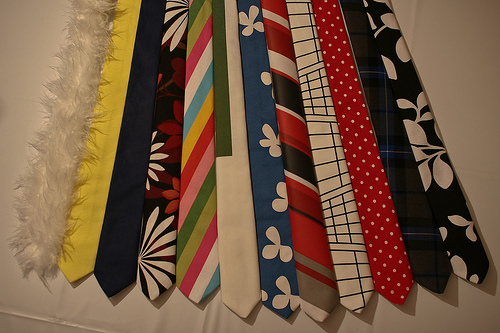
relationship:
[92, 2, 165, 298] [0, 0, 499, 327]
black tie laying on background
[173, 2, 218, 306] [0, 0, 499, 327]
necktie laying on background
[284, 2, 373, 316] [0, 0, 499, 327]
necktie laying on background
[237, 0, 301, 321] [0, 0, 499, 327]
necktie laying on background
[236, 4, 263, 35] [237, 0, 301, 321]
white flowers on necktie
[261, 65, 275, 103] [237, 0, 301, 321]
white flowers on necktie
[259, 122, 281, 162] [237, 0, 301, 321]
white flowers on necktie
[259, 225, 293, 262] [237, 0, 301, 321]
white flowers on necktie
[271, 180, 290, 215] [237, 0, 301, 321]
white flowers on necktie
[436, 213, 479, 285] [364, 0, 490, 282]
object on necktie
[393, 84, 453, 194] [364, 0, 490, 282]
object on necktie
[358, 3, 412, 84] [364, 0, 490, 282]
object on necktie